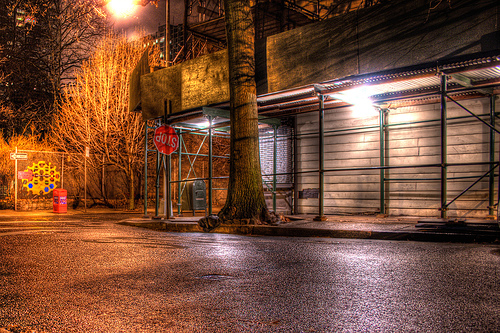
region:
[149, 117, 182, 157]
upside down stop sign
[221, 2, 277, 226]
trunk of a tree on the sidewalk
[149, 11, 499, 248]
an old abandoned building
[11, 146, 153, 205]
chain link fence beside the building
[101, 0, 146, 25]
bright light in the sky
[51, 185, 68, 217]
a pink trash can next to the fence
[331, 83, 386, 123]
light turned on the outside of the building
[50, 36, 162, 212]
bare trees growing on the ground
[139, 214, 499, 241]
sidewalk next to the building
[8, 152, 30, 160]
one way street sign on the fence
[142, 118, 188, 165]
The sign is upside down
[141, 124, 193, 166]
Red and white are the color of the sign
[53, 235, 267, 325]
This is the street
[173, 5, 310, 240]
One tree in the shot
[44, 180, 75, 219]
An orange and white cone in the shot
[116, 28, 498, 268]
This is a building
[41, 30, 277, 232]
Trees are on the side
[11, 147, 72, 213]
Yellow and blue on the gate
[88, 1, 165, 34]
A light circle in the shot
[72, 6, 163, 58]
This is nighttime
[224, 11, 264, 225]
the trunk of a tree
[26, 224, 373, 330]
the asphalt on the road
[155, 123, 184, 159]
a stop sign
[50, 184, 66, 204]
a red box on the ground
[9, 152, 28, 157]
a white sign on the fence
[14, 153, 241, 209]
a chain link fence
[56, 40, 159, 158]
a tree behind the fence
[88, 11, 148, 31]
the sky behind the trees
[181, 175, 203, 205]
a green can on the street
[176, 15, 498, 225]
a building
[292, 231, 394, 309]
reflection on the ground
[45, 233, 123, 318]
the ground is wet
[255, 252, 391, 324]
the street is asphalt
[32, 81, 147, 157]
the tree is bare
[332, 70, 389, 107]
the light is on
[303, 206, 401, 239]
the sidewalk is lit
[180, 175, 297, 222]
trunk of the tree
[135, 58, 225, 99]
wood on the side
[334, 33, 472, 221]
construction on the building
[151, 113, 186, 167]
stop sign on side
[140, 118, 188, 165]
stop sign hang off the pole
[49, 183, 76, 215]
newspaper stand on the corner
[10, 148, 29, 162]
one way sign on the fence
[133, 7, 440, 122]
green scaffolding above the ground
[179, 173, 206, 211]
Mail box on the corner